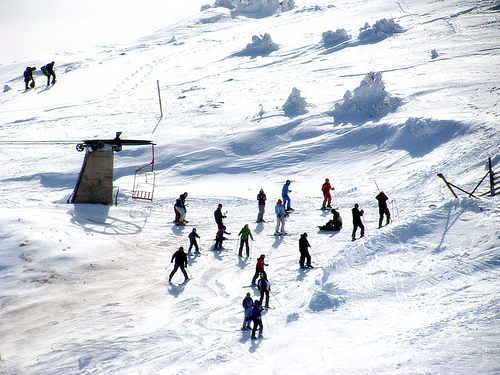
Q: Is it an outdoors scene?
A: Yes, it is outdoors.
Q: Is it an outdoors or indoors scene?
A: It is outdoors.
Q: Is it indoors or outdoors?
A: It is outdoors.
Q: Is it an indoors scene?
A: No, it is outdoors.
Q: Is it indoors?
A: No, it is outdoors.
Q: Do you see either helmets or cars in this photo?
A: No, there are no helmets or cars.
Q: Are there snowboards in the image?
A: No, there are no snowboards.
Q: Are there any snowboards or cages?
A: No, there are no snowboards or cages.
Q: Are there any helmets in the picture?
A: No, there are no helmets.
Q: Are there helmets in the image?
A: No, there are no helmets.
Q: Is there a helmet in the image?
A: No, there are no helmets.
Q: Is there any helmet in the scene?
A: No, there are no helmets.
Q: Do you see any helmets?
A: No, there are no helmets.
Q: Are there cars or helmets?
A: No, there are no helmets or cars.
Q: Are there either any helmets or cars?
A: No, there are no helmets or cars.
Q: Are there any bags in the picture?
A: No, there are no bags.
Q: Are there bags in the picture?
A: No, there are no bags.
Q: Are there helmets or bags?
A: No, there are no bags or helmets.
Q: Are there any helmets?
A: No, there are no helmets.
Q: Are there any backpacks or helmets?
A: No, there are no helmets or backpacks.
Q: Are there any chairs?
A: Yes, there is a chair.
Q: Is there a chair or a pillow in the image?
A: Yes, there is a chair.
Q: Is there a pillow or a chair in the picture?
A: Yes, there is a chair.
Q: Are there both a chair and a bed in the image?
A: No, there is a chair but no beds.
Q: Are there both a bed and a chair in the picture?
A: No, there is a chair but no beds.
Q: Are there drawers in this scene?
A: No, there are no drawers.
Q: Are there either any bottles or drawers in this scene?
A: No, there are no drawers or bottles.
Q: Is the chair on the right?
A: No, the chair is on the left of the image.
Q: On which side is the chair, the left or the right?
A: The chair is on the left of the image.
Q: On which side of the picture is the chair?
A: The chair is on the left of the image.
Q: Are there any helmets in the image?
A: No, there are no helmets.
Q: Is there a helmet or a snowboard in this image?
A: No, there are no helmets or snowboards.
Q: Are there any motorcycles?
A: No, there are no motorcycles.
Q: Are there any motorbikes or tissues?
A: No, there are no motorbikes or tissues.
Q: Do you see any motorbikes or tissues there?
A: No, there are no motorbikes or tissues.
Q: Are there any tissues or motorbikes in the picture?
A: No, there are no motorbikes or tissues.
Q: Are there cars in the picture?
A: No, there are no cars.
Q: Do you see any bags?
A: No, there are no bags.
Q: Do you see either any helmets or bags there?
A: No, there are no bags or helmets.